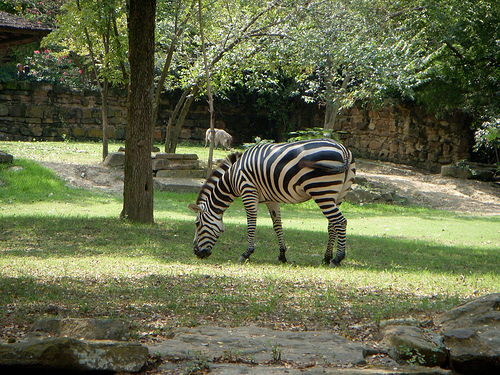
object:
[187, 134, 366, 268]
zebra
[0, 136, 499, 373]
grass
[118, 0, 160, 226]
tree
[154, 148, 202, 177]
outcropping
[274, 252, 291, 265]
hooves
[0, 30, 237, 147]
stone wall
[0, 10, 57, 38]
roof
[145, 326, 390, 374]
rocks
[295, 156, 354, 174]
tail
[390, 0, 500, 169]
shrub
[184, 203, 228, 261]
head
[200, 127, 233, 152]
animal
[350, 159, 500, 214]
path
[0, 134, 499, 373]
foreground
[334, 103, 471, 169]
rock wall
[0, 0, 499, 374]
zoo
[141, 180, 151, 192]
hole